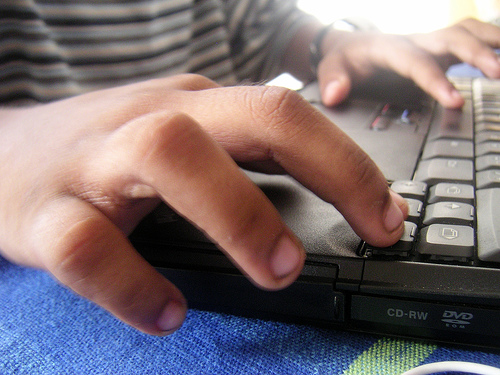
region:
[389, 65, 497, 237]
This is a laptop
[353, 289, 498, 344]
This is an optical drive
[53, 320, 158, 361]
These are blue jeans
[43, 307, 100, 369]
These are jeans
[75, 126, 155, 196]
This is a hand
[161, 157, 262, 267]
These are short fingers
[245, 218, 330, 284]
These are light nails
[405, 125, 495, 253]
This is a keyboard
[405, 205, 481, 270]
The keyboard has keys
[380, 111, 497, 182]
The keyboard is black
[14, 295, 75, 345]
this is a mat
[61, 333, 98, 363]
the mat is blue in color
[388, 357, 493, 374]
this is a wire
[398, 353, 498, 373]
the wire is white in color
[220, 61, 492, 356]
this is a keyboard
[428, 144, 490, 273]
these are several buttons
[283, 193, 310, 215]
the laptop is black in color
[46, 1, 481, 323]
the hands are on the laptop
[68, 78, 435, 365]
the fingers are big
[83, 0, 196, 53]
this is a t-shirt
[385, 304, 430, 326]
CD-RW printed on side of laptop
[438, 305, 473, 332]
DVD logo on side of laptop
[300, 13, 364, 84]
watch on boy's wrist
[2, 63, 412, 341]
boy's right hand on laptop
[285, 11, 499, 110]
boy's left hand on laptop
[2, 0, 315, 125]
striped shirt with blue lines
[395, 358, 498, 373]
white appliance cord on table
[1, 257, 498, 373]
blue table cloth with green stripe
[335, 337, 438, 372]
green stripe on blue woven table cloth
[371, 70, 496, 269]
keyboard portion of laptop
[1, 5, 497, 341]
peron typing on keyboard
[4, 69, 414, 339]
person's right hand on keyboard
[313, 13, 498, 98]
person's left hand on keyboard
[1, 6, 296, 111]
black, gray, and white shirt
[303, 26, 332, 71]
watch on person's wrist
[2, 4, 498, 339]
person wearing striped shisrt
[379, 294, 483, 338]
white lettering on black background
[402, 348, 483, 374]
white cord on table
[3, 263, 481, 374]
blue tablecloth under laptop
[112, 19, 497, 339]
black laptop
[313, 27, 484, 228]
This is a picture of a keyboard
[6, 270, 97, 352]
This is a picture of jeans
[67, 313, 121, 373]
The jeans are blue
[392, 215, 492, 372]
This is an optical drive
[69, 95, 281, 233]
This is a picture of a hand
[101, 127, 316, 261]
The fingers are short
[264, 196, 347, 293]
The nails are tiny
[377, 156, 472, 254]
This is a keyboard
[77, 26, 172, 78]
The shirt is striped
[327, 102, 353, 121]
This is a mouse